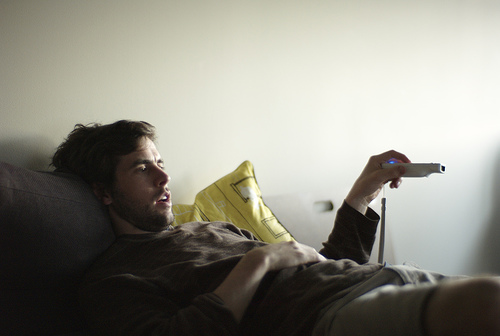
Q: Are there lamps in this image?
A: No, there are no lamps.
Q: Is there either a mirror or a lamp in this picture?
A: No, there are no lamps or mirrors.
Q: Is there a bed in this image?
A: Yes, there is a bed.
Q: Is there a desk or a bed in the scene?
A: Yes, there is a bed.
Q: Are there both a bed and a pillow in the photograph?
A: Yes, there are both a bed and a pillow.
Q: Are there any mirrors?
A: No, there are no mirrors.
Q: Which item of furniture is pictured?
A: The piece of furniture is a bed.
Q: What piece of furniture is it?
A: The piece of furniture is a bed.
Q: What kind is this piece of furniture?
A: This is a bed.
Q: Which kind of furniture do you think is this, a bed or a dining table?
A: This is a bed.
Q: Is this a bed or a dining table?
A: This is a bed.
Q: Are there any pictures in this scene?
A: No, there are no pictures.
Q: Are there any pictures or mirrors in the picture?
A: No, there are no pictures or mirrors.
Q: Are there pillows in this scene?
A: Yes, there is a pillow.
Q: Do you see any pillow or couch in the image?
A: Yes, there is a pillow.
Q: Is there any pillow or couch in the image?
A: Yes, there is a pillow.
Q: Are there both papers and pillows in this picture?
A: No, there is a pillow but no papers.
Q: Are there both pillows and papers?
A: No, there is a pillow but no papers.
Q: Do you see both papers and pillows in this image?
A: No, there is a pillow but no papers.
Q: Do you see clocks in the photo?
A: No, there are no clocks.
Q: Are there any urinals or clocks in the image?
A: No, there are no clocks or urinals.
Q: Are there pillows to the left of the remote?
A: Yes, there is a pillow to the left of the remote.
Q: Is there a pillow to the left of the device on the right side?
A: Yes, there is a pillow to the left of the remote.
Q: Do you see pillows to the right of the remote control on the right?
A: No, the pillow is to the left of the remote.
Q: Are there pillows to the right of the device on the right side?
A: No, the pillow is to the left of the remote.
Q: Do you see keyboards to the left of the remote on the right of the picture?
A: No, there is a pillow to the left of the remote control.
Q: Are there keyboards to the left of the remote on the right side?
A: No, there is a pillow to the left of the remote control.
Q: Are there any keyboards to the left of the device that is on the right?
A: No, there is a pillow to the left of the remote control.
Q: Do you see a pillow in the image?
A: Yes, there is a pillow.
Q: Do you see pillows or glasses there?
A: Yes, there is a pillow.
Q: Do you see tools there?
A: No, there are no tools.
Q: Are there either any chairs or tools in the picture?
A: No, there are no tools or chairs.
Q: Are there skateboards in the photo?
A: No, there are no skateboards.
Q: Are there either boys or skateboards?
A: No, there are no skateboards or boys.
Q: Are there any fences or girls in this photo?
A: No, there are no fences or girls.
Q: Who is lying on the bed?
A: The man is lying on the bed.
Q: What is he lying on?
A: The man is lying on the bed.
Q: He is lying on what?
A: The man is lying on the bed.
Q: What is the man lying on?
A: The man is lying on the bed.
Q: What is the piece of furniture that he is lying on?
A: The piece of furniture is a bed.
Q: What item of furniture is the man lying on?
A: The man is lying on the bed.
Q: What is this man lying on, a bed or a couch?
A: The man is lying on a bed.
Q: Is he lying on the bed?
A: Yes, the man is lying on the bed.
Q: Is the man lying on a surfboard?
A: No, the man is lying on the bed.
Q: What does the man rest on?
A: The man rests on the pillow.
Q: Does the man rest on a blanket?
A: No, the man rests on the pillow.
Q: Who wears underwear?
A: The man wears underwear.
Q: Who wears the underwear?
A: The man wears underwear.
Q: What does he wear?
A: The man wears underwear.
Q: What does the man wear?
A: The man wears underwear.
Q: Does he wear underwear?
A: Yes, the man wears underwear.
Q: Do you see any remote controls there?
A: Yes, there is a remote control.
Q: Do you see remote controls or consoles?
A: Yes, there is a remote control.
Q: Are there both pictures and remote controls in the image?
A: No, there is a remote control but no pictures.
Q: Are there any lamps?
A: No, there are no lamps.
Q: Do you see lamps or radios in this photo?
A: No, there are no lamps or radios.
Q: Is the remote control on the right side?
A: Yes, the remote control is on the right of the image.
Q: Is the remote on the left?
A: No, the remote is on the right of the image.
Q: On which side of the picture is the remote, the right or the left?
A: The remote is on the right of the image.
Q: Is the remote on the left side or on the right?
A: The remote is on the right of the image.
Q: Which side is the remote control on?
A: The remote control is on the right of the image.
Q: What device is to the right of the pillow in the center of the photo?
A: The device is a remote control.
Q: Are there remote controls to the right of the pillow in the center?
A: Yes, there is a remote control to the right of the pillow.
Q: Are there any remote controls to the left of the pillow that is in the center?
A: No, the remote control is to the right of the pillow.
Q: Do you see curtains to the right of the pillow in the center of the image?
A: No, there is a remote control to the right of the pillow.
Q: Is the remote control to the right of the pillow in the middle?
A: Yes, the remote control is to the right of the pillow.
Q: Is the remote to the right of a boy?
A: No, the remote is to the right of the pillow.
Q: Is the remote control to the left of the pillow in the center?
A: No, the remote control is to the right of the pillow.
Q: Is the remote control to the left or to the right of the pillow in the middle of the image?
A: The remote control is to the right of the pillow.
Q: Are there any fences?
A: No, there are no fences.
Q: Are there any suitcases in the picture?
A: No, there are no suitcases.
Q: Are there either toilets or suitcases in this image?
A: No, there are no suitcases or toilets.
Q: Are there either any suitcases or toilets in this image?
A: No, there are no suitcases or toilets.